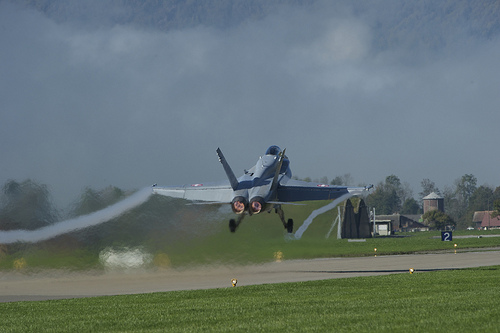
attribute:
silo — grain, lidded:
[418, 191, 446, 230]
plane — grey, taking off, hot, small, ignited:
[134, 139, 374, 230]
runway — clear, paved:
[0, 217, 499, 308]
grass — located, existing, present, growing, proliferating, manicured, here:
[9, 231, 497, 325]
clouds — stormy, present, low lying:
[0, 2, 498, 212]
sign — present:
[441, 229, 457, 245]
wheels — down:
[224, 211, 301, 232]